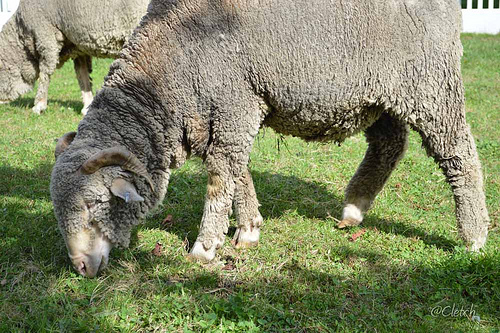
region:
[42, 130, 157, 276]
sheep eating grass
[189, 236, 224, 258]
the hoof is white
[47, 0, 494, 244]
sheep has gray wool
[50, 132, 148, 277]
head of a sheep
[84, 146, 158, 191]
horn of the sheep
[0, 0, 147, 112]
the sheep is eating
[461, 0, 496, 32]
there is a wall in the back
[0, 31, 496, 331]
grass on the ground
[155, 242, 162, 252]
the leaf is brown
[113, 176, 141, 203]
ear of a sheep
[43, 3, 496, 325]
sheep is eating grass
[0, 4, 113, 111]
sheep is eating grass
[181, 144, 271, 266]
front legs of sheep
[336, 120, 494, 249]
back legs of sheep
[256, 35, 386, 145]
bulky belly of sheep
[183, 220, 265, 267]
hooves of sheep are gray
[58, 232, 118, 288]
mouth on green grass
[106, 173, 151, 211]
ear on side the head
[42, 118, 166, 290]
head has two horns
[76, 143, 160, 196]
the horne is curved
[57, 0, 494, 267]
grey sheep grazing in grass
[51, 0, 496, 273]
large sheep grazing in field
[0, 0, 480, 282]
grey sheep eating grass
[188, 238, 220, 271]
white hoof of sheep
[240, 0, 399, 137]
furry grey body of sheep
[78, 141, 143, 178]
small horn on side of shep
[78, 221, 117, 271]
white snout of sheep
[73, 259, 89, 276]
pink nostril of sheep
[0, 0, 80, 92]
sheep grazing in field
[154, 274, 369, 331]
field of grass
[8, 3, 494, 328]
The sheep are out in a pasture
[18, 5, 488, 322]
The sheep are eating the grass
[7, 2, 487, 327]
A sheep is casting a shadow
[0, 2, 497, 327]
The sheep are raised for their wool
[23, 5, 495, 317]
The sheep belong to a farmer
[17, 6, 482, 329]
The sheep are out in the sunshine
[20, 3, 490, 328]
Some sheep are out in the daytime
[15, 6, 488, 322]
The sheep are watching for predators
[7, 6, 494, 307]
The sheep are male and female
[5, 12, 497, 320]
The sheep are enjoying the day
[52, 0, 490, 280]
A lamb grazing in the grass.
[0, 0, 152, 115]
A white lamb grazing.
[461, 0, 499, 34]
A white wall with windows.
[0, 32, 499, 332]
An area of pasture.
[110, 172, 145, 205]
A tan lambs ear.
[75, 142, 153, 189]
A male sheep horn.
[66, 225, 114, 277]
A white sheep snout.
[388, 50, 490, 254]
A rear sheep leg.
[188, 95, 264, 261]
A pair of front legs.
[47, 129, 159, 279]
A male sheep head.